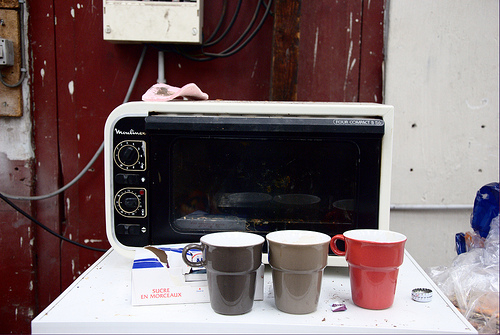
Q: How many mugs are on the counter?
A: Three.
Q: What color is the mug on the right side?
A: Red.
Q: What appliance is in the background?
A: Microwave.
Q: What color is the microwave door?
A: Black.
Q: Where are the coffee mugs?
A: On the counter.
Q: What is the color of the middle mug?
A: Light brown.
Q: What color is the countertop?
A: White.